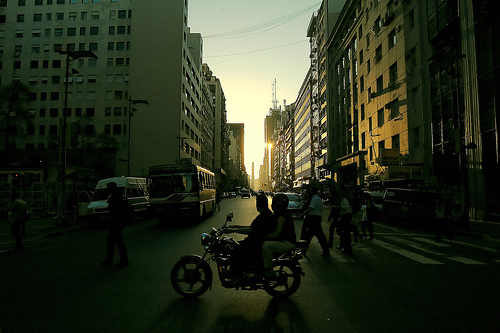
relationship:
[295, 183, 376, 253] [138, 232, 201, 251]
people crossing street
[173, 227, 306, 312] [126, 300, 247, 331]
motorcycle on road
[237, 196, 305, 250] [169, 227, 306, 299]
two people on motorcycle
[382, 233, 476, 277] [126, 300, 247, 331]
white lines on road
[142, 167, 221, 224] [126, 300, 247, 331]
bus on road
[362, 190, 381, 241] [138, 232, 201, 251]
woman crossing street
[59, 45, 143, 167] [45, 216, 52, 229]
streetlights on sidewalk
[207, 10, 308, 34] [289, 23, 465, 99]
powerlines over buildings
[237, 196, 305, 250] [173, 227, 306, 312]
two people on motorcycle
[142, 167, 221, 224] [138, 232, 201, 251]
bus stopped on street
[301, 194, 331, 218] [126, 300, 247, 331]
white shirt on road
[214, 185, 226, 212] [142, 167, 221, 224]
person walking behind bus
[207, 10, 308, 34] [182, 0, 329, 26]
powerlines running across tops of buildings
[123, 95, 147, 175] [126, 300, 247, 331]
streetlamps near road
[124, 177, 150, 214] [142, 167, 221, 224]
white van near bus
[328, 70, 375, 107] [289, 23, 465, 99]
windows on buildings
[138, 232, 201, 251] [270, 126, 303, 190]
street with apartment buildings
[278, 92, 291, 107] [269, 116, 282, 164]
flag pole on buildings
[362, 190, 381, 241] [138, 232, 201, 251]
woman standing in street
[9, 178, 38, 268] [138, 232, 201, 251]
man crossing street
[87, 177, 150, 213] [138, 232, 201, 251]
white van parked in street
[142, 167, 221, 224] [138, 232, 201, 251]
bus driving down street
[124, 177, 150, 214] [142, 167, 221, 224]
white van parked near bus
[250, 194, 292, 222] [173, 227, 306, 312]
man and woman on motorcycle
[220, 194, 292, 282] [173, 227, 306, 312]
man and woman riding motorcycle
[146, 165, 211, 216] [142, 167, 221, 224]
front of city bus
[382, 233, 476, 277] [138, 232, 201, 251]
white lines on street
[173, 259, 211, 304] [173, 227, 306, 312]
black tire on motorcycle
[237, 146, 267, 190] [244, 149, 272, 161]
light in distance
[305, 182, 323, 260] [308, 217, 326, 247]
person wearing black pants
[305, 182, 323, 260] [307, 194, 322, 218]
person wearing white shirt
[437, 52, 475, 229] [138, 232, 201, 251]
lamp post on street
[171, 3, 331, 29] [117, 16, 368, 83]
electrical wires between buildings